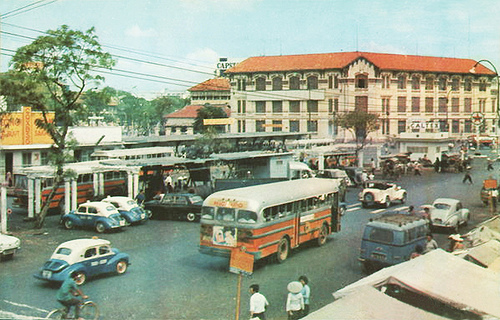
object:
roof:
[223, 51, 497, 76]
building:
[223, 51, 500, 139]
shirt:
[55, 279, 80, 303]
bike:
[44, 294, 99, 319]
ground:
[446, 182, 471, 196]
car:
[33, 236, 131, 287]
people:
[370, 158, 376, 174]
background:
[394, 131, 467, 164]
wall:
[234, 90, 325, 101]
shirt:
[249, 292, 269, 313]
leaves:
[31, 44, 42, 51]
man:
[248, 284, 269, 320]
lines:
[345, 202, 426, 214]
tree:
[0, 25, 116, 230]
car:
[59, 202, 126, 235]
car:
[100, 195, 148, 225]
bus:
[198, 178, 341, 264]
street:
[1, 151, 500, 319]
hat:
[286, 281, 303, 293]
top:
[202, 179, 339, 213]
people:
[285, 280, 305, 319]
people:
[298, 275, 311, 314]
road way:
[0, 190, 423, 319]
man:
[56, 272, 88, 319]